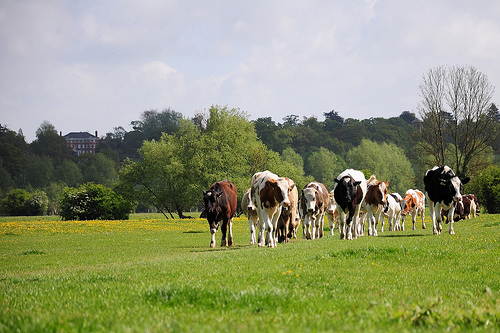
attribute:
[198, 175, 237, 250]
cow — dark brown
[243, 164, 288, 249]
cow — white, brown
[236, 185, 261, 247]
cow — brown, white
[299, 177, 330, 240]
cow — white, brown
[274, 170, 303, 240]
cow — brown, white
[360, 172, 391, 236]
cow — white, brown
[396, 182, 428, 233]
cow — brown, white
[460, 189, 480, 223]
cow — white, brown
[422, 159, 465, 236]
cow — black, white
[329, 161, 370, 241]
cow — white, black